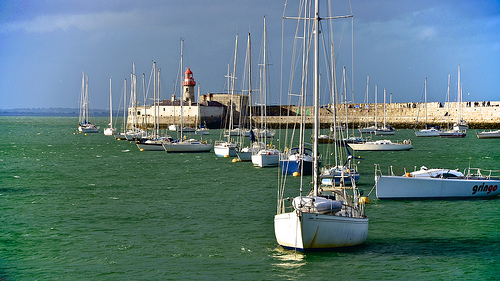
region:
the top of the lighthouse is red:
[180, 66, 195, 86]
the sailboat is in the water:
[261, 1, 371, 257]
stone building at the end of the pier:
[128, 99, 227, 140]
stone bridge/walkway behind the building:
[248, 106, 498, 129]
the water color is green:
[4, 117, 499, 276]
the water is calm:
[6, 117, 499, 278]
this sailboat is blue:
[278, 149, 320, 174]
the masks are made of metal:
[171, 39, 210, 146]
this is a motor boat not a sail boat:
[366, 163, 499, 206]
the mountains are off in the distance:
[1, 103, 123, 123]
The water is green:
[42, 153, 173, 262]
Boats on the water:
[65, 118, 492, 261]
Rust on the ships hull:
[307, 223, 360, 248]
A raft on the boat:
[293, 189, 344, 216]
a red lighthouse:
[183, 64, 194, 88]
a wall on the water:
[261, 95, 498, 127]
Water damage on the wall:
[420, 120, 498, 131]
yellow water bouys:
[217, 152, 239, 164]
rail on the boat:
[452, 163, 499, 178]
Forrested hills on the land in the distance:
[3, 103, 122, 115]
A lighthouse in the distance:
[161, 46, 214, 128]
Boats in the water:
[76, 91, 393, 253]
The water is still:
[19, 142, 230, 257]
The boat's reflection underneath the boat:
[247, 230, 355, 277]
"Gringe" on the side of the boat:
[452, 170, 499, 205]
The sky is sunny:
[13, 7, 448, 95]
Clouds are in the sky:
[309, 10, 448, 100]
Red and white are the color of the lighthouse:
[170, 55, 217, 103]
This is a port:
[239, 72, 499, 191]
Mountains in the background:
[7, 95, 113, 149]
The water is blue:
[63, 164, 170, 279]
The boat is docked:
[249, 174, 371, 279]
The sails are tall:
[36, 47, 208, 151]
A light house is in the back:
[162, 63, 212, 115]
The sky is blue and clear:
[26, 21, 148, 81]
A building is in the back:
[93, 82, 283, 172]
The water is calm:
[104, 165, 246, 266]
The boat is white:
[363, 152, 455, 204]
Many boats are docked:
[37, 91, 402, 275]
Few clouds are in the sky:
[42, 11, 111, 63]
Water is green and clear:
[13, 152, 222, 260]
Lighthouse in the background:
[170, 57, 222, 125]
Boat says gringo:
[452, 166, 496, 203]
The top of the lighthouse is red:
[167, 57, 212, 88]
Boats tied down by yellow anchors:
[218, 146, 304, 186]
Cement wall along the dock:
[255, 94, 498, 123]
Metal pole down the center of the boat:
[306, 3, 325, 205]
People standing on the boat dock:
[402, 96, 498, 109]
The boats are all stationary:
[52, 48, 498, 240]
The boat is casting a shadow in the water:
[344, 223, 499, 264]